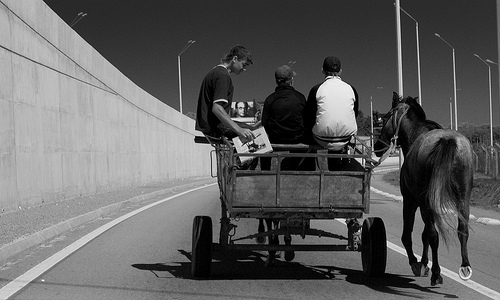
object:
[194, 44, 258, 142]
people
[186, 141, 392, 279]
wagon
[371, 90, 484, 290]
horse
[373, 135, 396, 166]
rope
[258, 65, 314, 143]
man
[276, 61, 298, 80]
cap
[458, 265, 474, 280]
horse shoe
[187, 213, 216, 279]
wheel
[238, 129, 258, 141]
hand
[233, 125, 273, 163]
magazine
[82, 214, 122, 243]
line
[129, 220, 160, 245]
street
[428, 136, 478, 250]
tail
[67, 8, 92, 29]
street light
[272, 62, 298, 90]
head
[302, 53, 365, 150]
man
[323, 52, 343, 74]
cap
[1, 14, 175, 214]
wall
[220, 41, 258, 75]
head